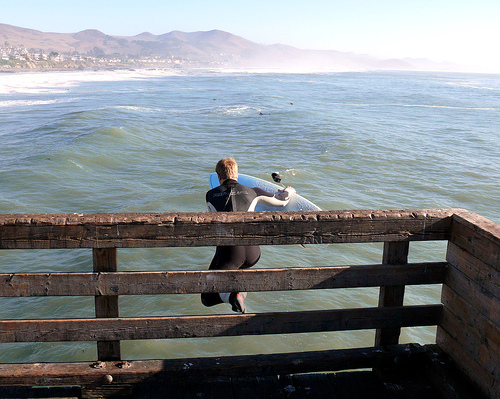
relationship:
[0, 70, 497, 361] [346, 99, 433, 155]
mounds on water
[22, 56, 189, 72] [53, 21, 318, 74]
homes along mountain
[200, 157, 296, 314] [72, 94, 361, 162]
human jumping into water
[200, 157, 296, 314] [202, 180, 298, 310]
human wearing wetsuit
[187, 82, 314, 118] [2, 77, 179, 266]
birds circling wave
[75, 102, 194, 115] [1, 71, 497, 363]
wave in water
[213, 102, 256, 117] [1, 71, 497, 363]
wave in water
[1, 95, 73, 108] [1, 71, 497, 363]
wave in water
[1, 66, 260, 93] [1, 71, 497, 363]
wave in water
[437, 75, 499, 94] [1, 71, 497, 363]
wave in water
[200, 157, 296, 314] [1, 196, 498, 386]
human jumping off dock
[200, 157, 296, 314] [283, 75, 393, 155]
human jumps into ocean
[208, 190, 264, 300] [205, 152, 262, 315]
wetsuit worn by human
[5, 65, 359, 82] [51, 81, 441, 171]
surf at edge of ocean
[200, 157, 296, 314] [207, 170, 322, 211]
human holding blue board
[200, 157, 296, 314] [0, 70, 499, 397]
human jumping into water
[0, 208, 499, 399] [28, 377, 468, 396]
railing on platform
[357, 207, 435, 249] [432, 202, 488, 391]
railing connected to wall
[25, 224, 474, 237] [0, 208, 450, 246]
cracks on rail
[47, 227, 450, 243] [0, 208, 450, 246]
lines on rail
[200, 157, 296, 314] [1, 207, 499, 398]
human jumping off dock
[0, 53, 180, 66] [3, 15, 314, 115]
homes in distance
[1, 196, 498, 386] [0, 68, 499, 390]
dock above ocean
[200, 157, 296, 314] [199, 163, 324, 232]
human holding surfboard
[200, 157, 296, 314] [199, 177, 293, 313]
human wearing wetsuit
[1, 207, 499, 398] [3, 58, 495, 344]
dock out across ocean